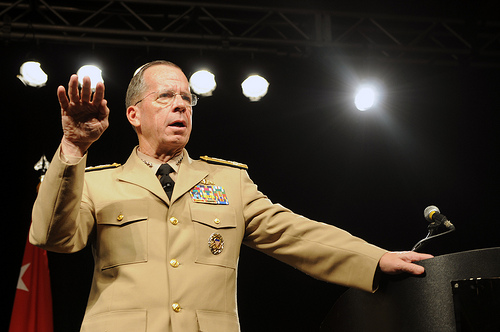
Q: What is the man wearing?
A: Uniform.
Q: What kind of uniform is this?
A: Military.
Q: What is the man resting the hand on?
A: Podium.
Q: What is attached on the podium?
A: Microphone.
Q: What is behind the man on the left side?
A: Flag.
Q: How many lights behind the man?
A: 5.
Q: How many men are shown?
A: 1.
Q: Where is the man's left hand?
A: On podium.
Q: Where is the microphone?
A: Near man's left hand.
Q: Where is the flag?
A: Behind the man.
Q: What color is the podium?
A: Black.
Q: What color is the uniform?
A: Tan.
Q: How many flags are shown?
A: 1.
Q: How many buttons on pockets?
A: 2.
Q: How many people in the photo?
A: One.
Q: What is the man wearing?
A: A uniform.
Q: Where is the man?
A: Under the lights.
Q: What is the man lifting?
A: A arm.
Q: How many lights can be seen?
A: 5.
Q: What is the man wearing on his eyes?
A: Glasses.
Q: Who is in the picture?
A: A man.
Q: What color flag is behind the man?
A: Red.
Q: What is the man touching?
A: A podium.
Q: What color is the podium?
A: Black.